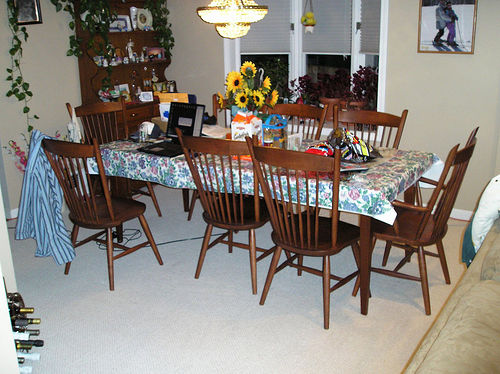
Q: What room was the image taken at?
A: It was taken at the dining room.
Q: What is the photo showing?
A: It is showing a dining room.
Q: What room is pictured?
A: It is a dining room.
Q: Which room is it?
A: It is a dining room.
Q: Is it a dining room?
A: Yes, it is a dining room.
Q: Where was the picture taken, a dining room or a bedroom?
A: It was taken at a dining room.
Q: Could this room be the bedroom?
A: No, it is the dining room.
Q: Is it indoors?
A: Yes, it is indoors.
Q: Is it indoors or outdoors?
A: It is indoors.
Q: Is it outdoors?
A: No, it is indoors.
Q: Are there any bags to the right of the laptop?
A: Yes, there are bags to the right of the laptop.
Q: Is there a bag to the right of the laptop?
A: Yes, there are bags to the right of the laptop.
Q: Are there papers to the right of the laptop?
A: No, there are bags to the right of the laptop.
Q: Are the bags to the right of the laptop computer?
A: Yes, the bags are to the right of the laptop computer.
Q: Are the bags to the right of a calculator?
A: No, the bags are to the right of the laptop computer.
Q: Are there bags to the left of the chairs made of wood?
A: Yes, there are bags to the left of the chairs.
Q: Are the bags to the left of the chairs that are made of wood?
A: Yes, the bags are to the left of the chairs.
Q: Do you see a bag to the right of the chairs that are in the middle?
A: Yes, there are bags to the right of the chairs.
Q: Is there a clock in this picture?
A: No, there are no clocks.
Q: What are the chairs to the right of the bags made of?
A: The chairs are made of wood.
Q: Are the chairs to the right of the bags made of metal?
A: No, the chairs are made of wood.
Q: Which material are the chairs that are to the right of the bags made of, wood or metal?
A: The chairs are made of wood.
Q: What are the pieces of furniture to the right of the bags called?
A: The pieces of furniture are chairs.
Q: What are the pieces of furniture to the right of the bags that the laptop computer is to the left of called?
A: The pieces of furniture are chairs.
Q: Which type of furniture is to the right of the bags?
A: The pieces of furniture are chairs.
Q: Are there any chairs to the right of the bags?
A: Yes, there are chairs to the right of the bags.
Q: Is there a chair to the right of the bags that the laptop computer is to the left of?
A: Yes, there are chairs to the right of the bags.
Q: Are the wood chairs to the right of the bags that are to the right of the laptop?
A: Yes, the chairs are to the right of the bags.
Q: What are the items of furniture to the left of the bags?
A: The pieces of furniture are chairs.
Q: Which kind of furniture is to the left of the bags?
A: The pieces of furniture are chairs.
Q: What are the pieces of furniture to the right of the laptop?
A: The pieces of furniture are chairs.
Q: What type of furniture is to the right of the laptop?
A: The pieces of furniture are chairs.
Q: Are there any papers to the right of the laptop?
A: No, there are chairs to the right of the laptop.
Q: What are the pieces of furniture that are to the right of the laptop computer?
A: The pieces of furniture are chairs.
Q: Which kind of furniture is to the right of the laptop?
A: The pieces of furniture are chairs.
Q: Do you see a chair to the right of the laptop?
A: Yes, there are chairs to the right of the laptop.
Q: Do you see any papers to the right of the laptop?
A: No, there are chairs to the right of the laptop.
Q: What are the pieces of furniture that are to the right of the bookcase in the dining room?
A: The pieces of furniture are chairs.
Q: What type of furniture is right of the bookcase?
A: The pieces of furniture are chairs.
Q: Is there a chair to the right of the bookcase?
A: Yes, there are chairs to the right of the bookcase.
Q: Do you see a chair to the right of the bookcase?
A: Yes, there are chairs to the right of the bookcase.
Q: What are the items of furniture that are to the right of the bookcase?
A: The pieces of furniture are chairs.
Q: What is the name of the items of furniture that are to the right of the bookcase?
A: The pieces of furniture are chairs.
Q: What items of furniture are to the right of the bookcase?
A: The pieces of furniture are chairs.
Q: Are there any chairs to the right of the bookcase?
A: Yes, there are chairs to the right of the bookcase.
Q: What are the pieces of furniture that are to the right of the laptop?
A: The pieces of furniture are chairs.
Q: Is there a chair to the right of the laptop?
A: Yes, there are chairs to the right of the laptop.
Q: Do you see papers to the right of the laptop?
A: No, there are chairs to the right of the laptop.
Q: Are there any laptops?
A: Yes, there is a laptop.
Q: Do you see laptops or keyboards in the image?
A: Yes, there is a laptop.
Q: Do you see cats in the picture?
A: No, there are no cats.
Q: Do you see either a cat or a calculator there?
A: No, there are no cats or calculators.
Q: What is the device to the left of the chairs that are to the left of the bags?
A: The device is a laptop.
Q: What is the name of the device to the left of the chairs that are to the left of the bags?
A: The device is a laptop.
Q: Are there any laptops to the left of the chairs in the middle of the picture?
A: Yes, there is a laptop to the left of the chairs.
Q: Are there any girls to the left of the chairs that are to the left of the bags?
A: No, there is a laptop to the left of the chairs.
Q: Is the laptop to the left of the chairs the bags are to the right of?
A: Yes, the laptop is to the left of the chairs.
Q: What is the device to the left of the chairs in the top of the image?
A: The device is a laptop.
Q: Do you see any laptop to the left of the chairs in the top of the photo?
A: Yes, there is a laptop to the left of the chairs.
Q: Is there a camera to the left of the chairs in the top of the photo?
A: No, there is a laptop to the left of the chairs.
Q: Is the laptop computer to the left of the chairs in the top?
A: Yes, the laptop computer is to the left of the chairs.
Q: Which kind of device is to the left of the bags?
A: The device is a laptop.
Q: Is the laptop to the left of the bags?
A: Yes, the laptop is to the left of the bags.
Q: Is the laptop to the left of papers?
A: No, the laptop is to the left of the bags.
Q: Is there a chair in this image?
A: Yes, there is a chair.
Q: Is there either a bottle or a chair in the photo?
A: Yes, there is a chair.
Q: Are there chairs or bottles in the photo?
A: Yes, there is a chair.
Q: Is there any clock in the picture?
A: No, there are no clocks.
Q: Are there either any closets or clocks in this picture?
A: No, there are no clocks or closets.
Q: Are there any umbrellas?
A: No, there are no umbrellas.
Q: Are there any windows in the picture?
A: Yes, there is a window.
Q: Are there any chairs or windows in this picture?
A: Yes, there is a window.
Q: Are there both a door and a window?
A: No, there is a window but no doors.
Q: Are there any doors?
A: No, there are no doors.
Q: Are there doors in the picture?
A: No, there are no doors.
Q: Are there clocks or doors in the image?
A: No, there are no doors or clocks.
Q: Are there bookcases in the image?
A: Yes, there is a bookcase.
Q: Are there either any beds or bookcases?
A: Yes, there is a bookcase.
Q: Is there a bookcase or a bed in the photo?
A: Yes, there is a bookcase.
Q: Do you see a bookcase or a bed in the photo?
A: Yes, there is a bookcase.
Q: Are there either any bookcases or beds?
A: Yes, there is a bookcase.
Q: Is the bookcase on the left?
A: Yes, the bookcase is on the left of the image.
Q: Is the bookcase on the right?
A: No, the bookcase is on the left of the image.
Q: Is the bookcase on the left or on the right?
A: The bookcase is on the left of the image.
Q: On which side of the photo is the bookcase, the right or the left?
A: The bookcase is on the left of the image.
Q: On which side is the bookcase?
A: The bookcase is on the left of the image.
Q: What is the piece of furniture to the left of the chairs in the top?
A: The piece of furniture is a bookcase.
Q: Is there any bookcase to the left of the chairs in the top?
A: Yes, there is a bookcase to the left of the chairs.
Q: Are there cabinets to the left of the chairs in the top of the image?
A: No, there is a bookcase to the left of the chairs.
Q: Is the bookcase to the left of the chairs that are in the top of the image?
A: Yes, the bookcase is to the left of the chairs.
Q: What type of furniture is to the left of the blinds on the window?
A: The piece of furniture is a bookcase.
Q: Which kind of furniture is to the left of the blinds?
A: The piece of furniture is a bookcase.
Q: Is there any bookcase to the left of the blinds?
A: Yes, there is a bookcase to the left of the blinds.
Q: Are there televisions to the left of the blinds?
A: No, there is a bookcase to the left of the blinds.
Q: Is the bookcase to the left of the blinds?
A: Yes, the bookcase is to the left of the blinds.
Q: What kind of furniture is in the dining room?
A: The piece of furniture is a bookcase.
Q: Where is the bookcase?
A: The bookcase is in the dining room.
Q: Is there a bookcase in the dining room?
A: Yes, there is a bookcase in the dining room.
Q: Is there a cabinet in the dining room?
A: No, there is a bookcase in the dining room.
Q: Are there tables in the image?
A: Yes, there is a table.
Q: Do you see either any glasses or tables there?
A: Yes, there is a table.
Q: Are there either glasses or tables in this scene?
A: Yes, there is a table.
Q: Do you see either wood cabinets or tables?
A: Yes, there is a wood table.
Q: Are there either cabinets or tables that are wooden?
A: Yes, the table is wooden.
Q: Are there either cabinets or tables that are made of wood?
A: Yes, the table is made of wood.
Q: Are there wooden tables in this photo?
A: Yes, there is a wood table.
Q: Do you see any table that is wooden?
A: Yes, there is a table that is wooden.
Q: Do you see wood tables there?
A: Yes, there is a table that is made of wood.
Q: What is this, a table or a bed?
A: This is a table.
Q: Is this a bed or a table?
A: This is a table.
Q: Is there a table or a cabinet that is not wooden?
A: No, there is a table but it is wooden.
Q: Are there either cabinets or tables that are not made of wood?
A: No, there is a table but it is made of wood.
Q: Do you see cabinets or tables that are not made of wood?
A: No, there is a table but it is made of wood.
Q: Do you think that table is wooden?
A: Yes, the table is wooden.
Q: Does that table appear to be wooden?
A: Yes, the table is wooden.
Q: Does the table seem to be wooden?
A: Yes, the table is wooden.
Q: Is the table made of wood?
A: Yes, the table is made of wood.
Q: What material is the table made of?
A: The table is made of wood.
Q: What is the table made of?
A: The table is made of wood.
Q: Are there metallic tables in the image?
A: No, there is a table but it is wooden.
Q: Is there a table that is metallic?
A: No, there is a table but it is wooden.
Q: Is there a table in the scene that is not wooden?
A: No, there is a table but it is wooden.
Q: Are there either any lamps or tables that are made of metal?
A: No, there is a table but it is made of wood.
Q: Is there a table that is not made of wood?
A: No, there is a table but it is made of wood.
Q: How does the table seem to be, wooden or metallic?
A: The table is wooden.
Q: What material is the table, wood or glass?
A: The table is made of wood.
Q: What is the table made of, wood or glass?
A: The table is made of wood.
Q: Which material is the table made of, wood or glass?
A: The table is made of wood.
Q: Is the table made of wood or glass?
A: The table is made of wood.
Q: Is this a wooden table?
A: Yes, this is a wooden table.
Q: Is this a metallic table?
A: No, this is a wooden table.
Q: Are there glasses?
A: No, there are no glasses.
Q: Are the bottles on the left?
A: Yes, the bottles are on the left of the image.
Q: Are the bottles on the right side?
A: No, the bottles are on the left of the image.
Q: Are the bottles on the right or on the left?
A: The bottles are on the left of the image.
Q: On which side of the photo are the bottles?
A: The bottles are on the left of the image.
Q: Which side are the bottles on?
A: The bottles are on the left of the image.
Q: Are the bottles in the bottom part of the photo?
A: Yes, the bottles are in the bottom of the image.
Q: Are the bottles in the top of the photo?
A: No, the bottles are in the bottom of the image.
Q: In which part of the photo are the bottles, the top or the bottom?
A: The bottles are in the bottom of the image.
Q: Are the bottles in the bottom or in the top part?
A: The bottles are in the bottom of the image.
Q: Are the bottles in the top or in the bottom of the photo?
A: The bottles are in the bottom of the image.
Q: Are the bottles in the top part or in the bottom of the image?
A: The bottles are in the bottom of the image.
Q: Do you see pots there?
A: No, there are no pots.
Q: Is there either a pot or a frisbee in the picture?
A: No, there are no pots or frisbees.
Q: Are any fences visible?
A: No, there are no fences.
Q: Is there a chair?
A: Yes, there is a chair.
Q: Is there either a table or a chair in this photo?
A: Yes, there is a chair.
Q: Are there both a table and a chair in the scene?
A: Yes, there are both a chair and a table.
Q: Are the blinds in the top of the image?
A: Yes, the blinds are in the top of the image.